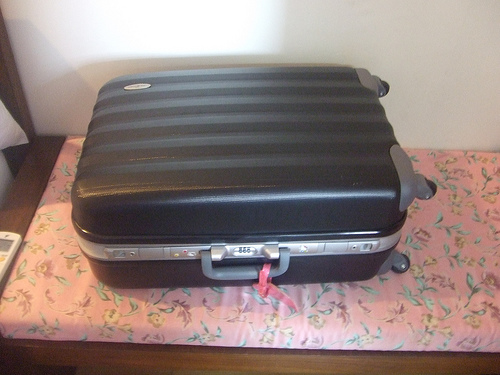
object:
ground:
[312, 171, 398, 225]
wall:
[2, 3, 499, 153]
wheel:
[416, 177, 438, 200]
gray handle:
[201, 244, 291, 281]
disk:
[124, 83, 152, 91]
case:
[70, 66, 437, 290]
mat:
[56, 132, 469, 344]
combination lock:
[233, 247, 258, 257]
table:
[0, 133, 497, 375]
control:
[0, 230, 22, 280]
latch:
[344, 241, 380, 254]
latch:
[104, 248, 139, 262]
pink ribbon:
[252, 263, 300, 313]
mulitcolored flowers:
[333, 297, 428, 335]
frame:
[1, 337, 500, 375]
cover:
[0, 134, 499, 353]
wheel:
[381, 79, 390, 97]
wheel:
[392, 253, 410, 274]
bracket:
[355, 67, 389, 98]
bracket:
[399, 167, 439, 211]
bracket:
[378, 250, 410, 276]